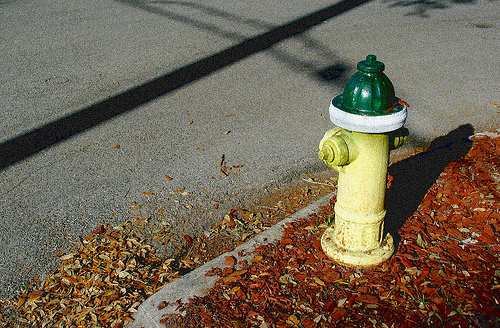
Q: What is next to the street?
A: Fire hydrant.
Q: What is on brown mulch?
A: Fire hydrant.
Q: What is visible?
A: A hydrant.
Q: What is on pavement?
A: Leaves.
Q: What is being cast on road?
A: A shadow.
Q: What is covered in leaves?
A: A sidewalk.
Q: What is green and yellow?
A: Fire hydrant.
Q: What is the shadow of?
A: Fire hydrant.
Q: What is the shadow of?
A: Electric pole.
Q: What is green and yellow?
A: Fire hydrant.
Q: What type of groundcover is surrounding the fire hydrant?
A: Mulch chips.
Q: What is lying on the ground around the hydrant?
A: Leaves.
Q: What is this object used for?
A: Put out fires.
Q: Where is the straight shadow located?
A: In the road.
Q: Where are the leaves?
A: Sidewalk.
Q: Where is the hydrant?
A: On sidewalk.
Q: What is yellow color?
A: Hydrant.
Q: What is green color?
A: Hydrant.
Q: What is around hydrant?
A: Leaves.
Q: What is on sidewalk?
A: Hydrant.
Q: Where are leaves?
A: Ground.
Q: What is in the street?
A: Leaves.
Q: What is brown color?
A: Leaves.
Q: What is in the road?
A: Leaves.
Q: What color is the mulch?
A: Red.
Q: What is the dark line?
A: A shadow.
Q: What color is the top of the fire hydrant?
A: Green.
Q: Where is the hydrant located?
A: Near a road.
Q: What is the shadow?
A: Telephone pole.